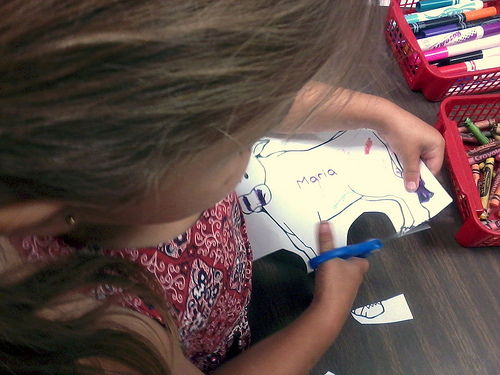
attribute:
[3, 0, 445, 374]
girl — cutting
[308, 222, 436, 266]
pair — blue, scissors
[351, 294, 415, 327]
piece — cut off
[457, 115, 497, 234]
crayons — colors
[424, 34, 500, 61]
marker — pink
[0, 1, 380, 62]
top — child's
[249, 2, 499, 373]
table — brown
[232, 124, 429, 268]
drawing — cow, black, maria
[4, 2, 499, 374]
picture — indoors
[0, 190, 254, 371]
shirt — patterned